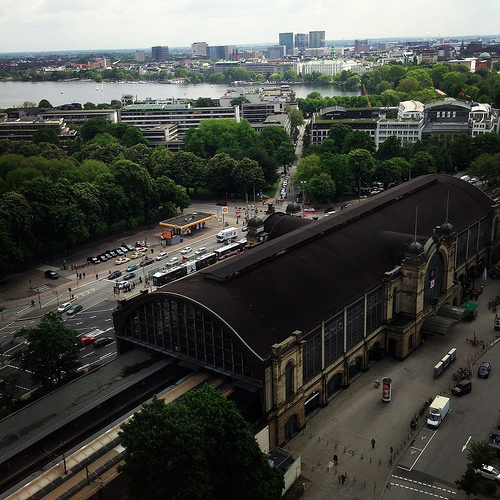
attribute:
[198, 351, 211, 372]
window — glass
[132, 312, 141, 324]
window — glass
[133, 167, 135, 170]
lead — green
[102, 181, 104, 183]
lead — green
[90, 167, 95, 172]
lead — green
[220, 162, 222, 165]
lead — green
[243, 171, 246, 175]
lead — green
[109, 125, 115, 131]
leaf — green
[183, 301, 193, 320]
window — glass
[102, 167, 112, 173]
leaf — green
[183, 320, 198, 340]
window — glass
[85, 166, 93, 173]
leaf — green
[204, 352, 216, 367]
window — glass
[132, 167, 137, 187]
leaf — green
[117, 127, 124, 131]
leaf — green